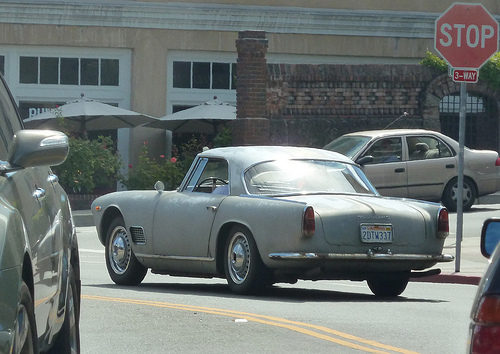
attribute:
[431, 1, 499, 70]
stop sign — octagonal, red, white, 3 way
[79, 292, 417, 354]
lines — yellow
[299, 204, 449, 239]
tail lights — oval, red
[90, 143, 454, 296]
car — old fashioned, grey, old, classic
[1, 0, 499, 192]
building — grey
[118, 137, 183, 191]
plant — green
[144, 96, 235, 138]
umbrella — white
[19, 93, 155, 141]
umbrella — white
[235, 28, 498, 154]
wall — brick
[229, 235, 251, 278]
hubcap — shiny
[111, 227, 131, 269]
hubcap — shiny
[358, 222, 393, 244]
license plate — black, white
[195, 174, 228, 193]
steering wheel — black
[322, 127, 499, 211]
car — gold, light colored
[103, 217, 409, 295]
wheels — black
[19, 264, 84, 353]
wheels — black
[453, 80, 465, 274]
post — grey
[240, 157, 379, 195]
back window — glared